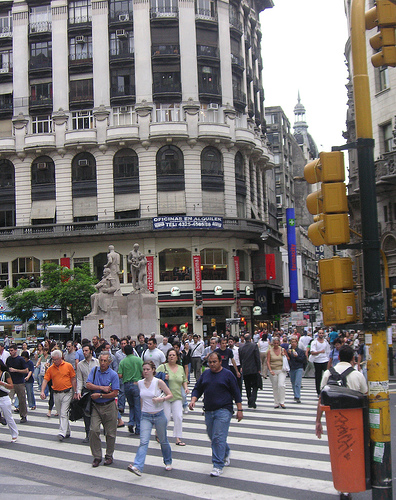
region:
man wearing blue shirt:
[84, 349, 119, 464]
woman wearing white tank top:
[128, 350, 176, 477]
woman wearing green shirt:
[162, 342, 191, 444]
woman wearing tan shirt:
[261, 333, 295, 394]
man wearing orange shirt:
[38, 349, 73, 441]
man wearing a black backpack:
[317, 332, 357, 445]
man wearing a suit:
[237, 326, 266, 417]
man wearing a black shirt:
[210, 332, 242, 393]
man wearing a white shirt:
[185, 327, 202, 370]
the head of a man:
[198, 334, 243, 377]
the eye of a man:
[199, 340, 230, 375]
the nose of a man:
[201, 335, 241, 372]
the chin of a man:
[197, 347, 223, 377]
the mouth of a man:
[194, 349, 230, 377]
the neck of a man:
[194, 341, 227, 380]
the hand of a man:
[179, 393, 201, 417]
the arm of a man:
[177, 361, 205, 411]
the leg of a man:
[193, 398, 243, 487]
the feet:
[196, 442, 241, 482]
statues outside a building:
[61, 231, 200, 385]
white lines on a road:
[233, 413, 320, 495]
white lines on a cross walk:
[21, 397, 260, 497]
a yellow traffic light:
[288, 139, 384, 363]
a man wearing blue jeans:
[190, 336, 258, 477]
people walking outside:
[31, 312, 293, 459]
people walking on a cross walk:
[46, 337, 305, 481]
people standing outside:
[51, 313, 238, 452]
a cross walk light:
[300, 239, 392, 491]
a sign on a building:
[124, 205, 247, 256]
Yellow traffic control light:
[302, 148, 352, 248]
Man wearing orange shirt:
[41, 350, 75, 439]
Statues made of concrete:
[82, 242, 158, 326]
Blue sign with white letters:
[150, 214, 225, 228]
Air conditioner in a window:
[76, 35, 86, 44]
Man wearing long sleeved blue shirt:
[188, 349, 246, 468]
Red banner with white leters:
[194, 251, 201, 287]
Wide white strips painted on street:
[245, 407, 315, 489]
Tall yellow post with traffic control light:
[301, 20, 388, 477]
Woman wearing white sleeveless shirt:
[126, 359, 173, 484]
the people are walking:
[88, 348, 234, 439]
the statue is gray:
[107, 253, 149, 313]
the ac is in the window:
[110, 25, 133, 43]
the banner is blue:
[172, 217, 196, 226]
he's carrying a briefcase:
[70, 392, 82, 412]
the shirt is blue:
[95, 376, 108, 384]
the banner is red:
[266, 256, 275, 275]